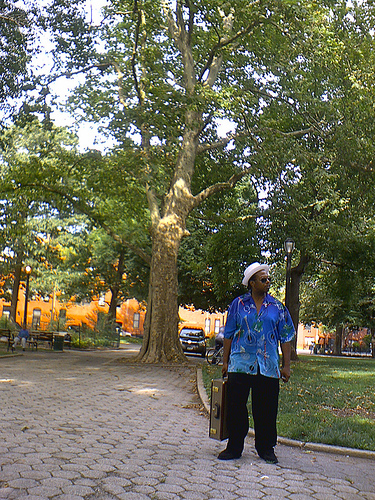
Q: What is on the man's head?
A: Hat.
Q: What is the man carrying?
A: A suitcase.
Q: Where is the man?
A: Park.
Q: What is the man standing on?
A: Concrete pavement.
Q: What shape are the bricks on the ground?
A: Octagon.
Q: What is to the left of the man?
A: Tree.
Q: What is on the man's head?
A: Hat.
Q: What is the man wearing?
A: Blue shirt and black pants.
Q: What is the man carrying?
A: Briefcase.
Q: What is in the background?
A: Buildings.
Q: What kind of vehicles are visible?
A: Suv.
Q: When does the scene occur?
A: Daytime.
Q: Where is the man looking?
A: To the right.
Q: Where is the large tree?
A: Behind the man.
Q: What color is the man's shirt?
A: Blue.